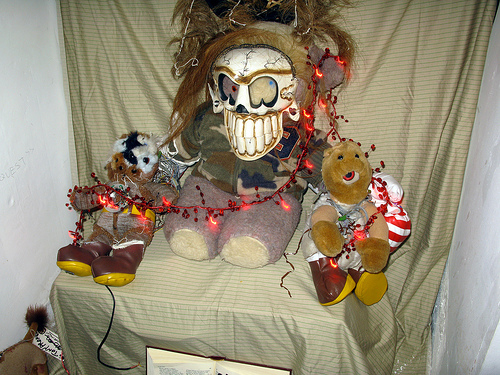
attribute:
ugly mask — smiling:
[168, 0, 358, 162]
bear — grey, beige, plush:
[156, 20, 337, 272]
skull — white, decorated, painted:
[205, 19, 300, 201]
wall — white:
[475, 141, 497, 363]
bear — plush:
[56, 140, 176, 307]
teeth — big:
[215, 87, 280, 171]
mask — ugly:
[206, 46, 301, 164]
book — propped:
[142, 344, 290, 373]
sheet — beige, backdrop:
[61, 3, 498, 370]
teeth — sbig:
[219, 111, 279, 151]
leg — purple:
[222, 214, 296, 266]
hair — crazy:
[163, 3, 365, 80]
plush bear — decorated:
[315, 143, 399, 298]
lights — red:
[69, 43, 384, 268]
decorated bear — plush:
[161, 0, 303, 276]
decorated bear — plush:
[304, 139, 389, 304]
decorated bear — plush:
[63, 127, 179, 289]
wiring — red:
[138, 74, 373, 225]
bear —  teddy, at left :
[65, 141, 192, 281]